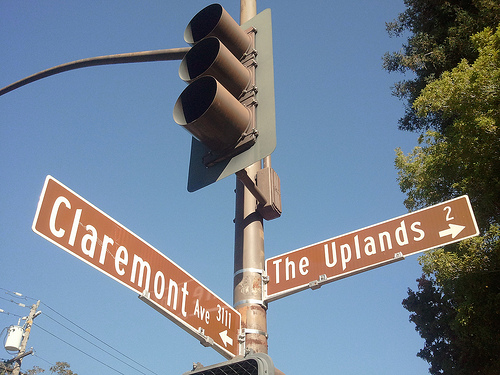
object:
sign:
[30, 173, 241, 360]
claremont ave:
[48, 195, 212, 326]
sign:
[261, 195, 481, 308]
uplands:
[271, 215, 427, 290]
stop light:
[172, 3, 277, 193]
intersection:
[30, 173, 480, 362]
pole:
[9, 298, 42, 374]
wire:
[42, 302, 156, 374]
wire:
[41, 310, 146, 374]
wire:
[34, 322, 123, 374]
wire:
[32, 353, 68, 374]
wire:
[3, 296, 24, 308]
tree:
[391, 62, 499, 346]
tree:
[383, 1, 499, 137]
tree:
[401, 272, 483, 374]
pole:
[231, 0, 268, 361]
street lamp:
[0, 45, 194, 98]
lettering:
[271, 206, 466, 285]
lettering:
[47, 196, 234, 348]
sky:
[0, 1, 500, 375]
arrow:
[218, 328, 234, 347]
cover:
[172, 74, 253, 154]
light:
[183, 3, 253, 61]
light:
[178, 35, 252, 100]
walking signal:
[180, 351, 274, 374]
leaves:
[381, 48, 414, 75]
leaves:
[409, 57, 473, 121]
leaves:
[401, 286, 427, 319]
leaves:
[469, 26, 500, 60]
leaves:
[384, 11, 410, 39]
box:
[3, 324, 24, 353]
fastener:
[234, 267, 265, 278]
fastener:
[233, 299, 268, 312]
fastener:
[241, 327, 268, 339]